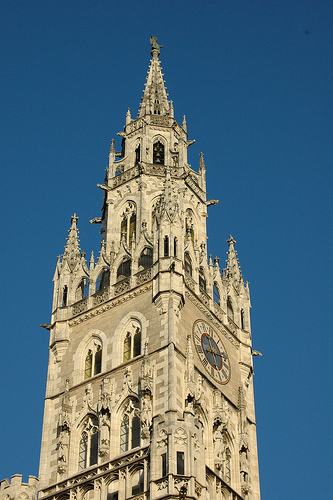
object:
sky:
[0, 1, 332, 500]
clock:
[192, 318, 230, 385]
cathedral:
[0, 34, 263, 500]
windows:
[130, 416, 140, 448]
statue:
[149, 35, 163, 51]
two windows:
[118, 209, 136, 246]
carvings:
[56, 424, 70, 472]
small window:
[154, 139, 164, 167]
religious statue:
[212, 423, 226, 470]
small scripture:
[156, 478, 168, 490]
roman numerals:
[199, 356, 209, 371]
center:
[201, 334, 222, 370]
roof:
[137, 36, 173, 120]